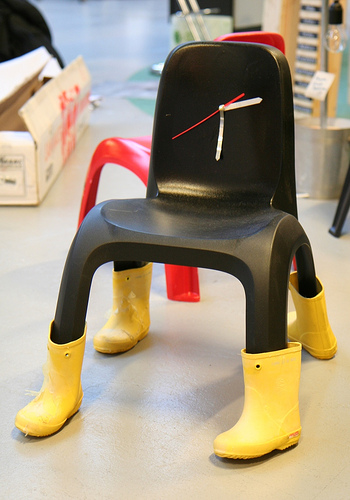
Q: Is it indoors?
A: Yes, it is indoors.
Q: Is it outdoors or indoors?
A: It is indoors.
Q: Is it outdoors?
A: No, it is indoors.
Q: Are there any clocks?
A: Yes, there is a clock.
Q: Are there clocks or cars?
A: Yes, there is a clock.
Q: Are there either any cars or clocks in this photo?
A: Yes, there is a clock.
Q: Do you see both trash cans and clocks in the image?
A: No, there is a clock but no trash cans.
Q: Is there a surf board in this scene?
A: No, there are no surfboards.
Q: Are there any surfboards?
A: No, there are no surfboards.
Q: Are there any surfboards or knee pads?
A: No, there are no surfboards or knee pads.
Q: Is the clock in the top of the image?
A: Yes, the clock is in the top of the image.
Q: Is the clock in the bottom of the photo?
A: No, the clock is in the top of the image.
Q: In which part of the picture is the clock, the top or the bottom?
A: The clock is in the top of the image.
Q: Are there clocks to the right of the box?
A: Yes, there is a clock to the right of the box.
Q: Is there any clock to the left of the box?
A: No, the clock is to the right of the box.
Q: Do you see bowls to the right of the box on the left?
A: No, there is a clock to the right of the box.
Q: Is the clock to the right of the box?
A: Yes, the clock is to the right of the box.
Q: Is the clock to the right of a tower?
A: No, the clock is to the right of the box.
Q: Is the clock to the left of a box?
A: No, the clock is to the right of a box.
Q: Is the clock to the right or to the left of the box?
A: The clock is to the right of the box.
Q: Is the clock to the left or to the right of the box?
A: The clock is to the right of the box.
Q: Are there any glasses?
A: No, there are no glasses.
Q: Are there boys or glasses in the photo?
A: No, there are no glasses or boys.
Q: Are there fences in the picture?
A: No, there are no fences.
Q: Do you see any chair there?
A: Yes, there is a chair.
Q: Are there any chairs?
A: Yes, there is a chair.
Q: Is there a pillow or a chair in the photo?
A: Yes, there is a chair.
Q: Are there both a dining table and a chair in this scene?
A: No, there is a chair but no dining tables.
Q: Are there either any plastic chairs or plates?
A: Yes, there is a plastic chair.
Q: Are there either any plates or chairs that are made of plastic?
A: Yes, the chair is made of plastic.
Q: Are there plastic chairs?
A: Yes, there is a chair that is made of plastic.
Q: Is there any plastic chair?
A: Yes, there is a chair that is made of plastic.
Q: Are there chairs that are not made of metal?
A: Yes, there is a chair that is made of plastic.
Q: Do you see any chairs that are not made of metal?
A: Yes, there is a chair that is made of plastic.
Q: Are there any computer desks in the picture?
A: No, there are no computer desks.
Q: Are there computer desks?
A: No, there are no computer desks.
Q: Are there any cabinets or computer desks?
A: No, there are no computer desks or cabinets.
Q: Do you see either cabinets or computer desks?
A: No, there are no computer desks or cabinets.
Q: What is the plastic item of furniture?
A: The piece of furniture is a chair.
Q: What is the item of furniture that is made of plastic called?
A: The piece of furniture is a chair.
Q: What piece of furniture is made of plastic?
A: The piece of furniture is a chair.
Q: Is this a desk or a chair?
A: This is a chair.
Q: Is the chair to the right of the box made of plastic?
A: Yes, the chair is made of plastic.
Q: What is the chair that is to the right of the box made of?
A: The chair is made of plastic.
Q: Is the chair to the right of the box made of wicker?
A: No, the chair is made of plastic.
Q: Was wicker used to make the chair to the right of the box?
A: No, the chair is made of plastic.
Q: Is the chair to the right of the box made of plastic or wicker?
A: The chair is made of plastic.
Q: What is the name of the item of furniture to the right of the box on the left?
A: The piece of furniture is a chair.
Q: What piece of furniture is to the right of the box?
A: The piece of furniture is a chair.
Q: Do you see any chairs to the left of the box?
A: No, the chair is to the right of the box.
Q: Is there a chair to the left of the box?
A: No, the chair is to the right of the box.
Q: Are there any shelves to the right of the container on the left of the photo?
A: No, there is a chair to the right of the box.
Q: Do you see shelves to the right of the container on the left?
A: No, there is a chair to the right of the box.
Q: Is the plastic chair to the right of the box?
A: Yes, the chair is to the right of the box.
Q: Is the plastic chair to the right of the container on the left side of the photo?
A: Yes, the chair is to the right of the box.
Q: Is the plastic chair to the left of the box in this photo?
A: No, the chair is to the right of the box.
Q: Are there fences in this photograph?
A: No, there are no fences.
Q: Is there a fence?
A: No, there are no fences.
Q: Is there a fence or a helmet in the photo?
A: No, there are no fences or helmets.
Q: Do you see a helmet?
A: No, there are no helmets.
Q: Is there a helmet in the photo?
A: No, there are no helmets.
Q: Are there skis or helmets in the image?
A: No, there are no helmets or skis.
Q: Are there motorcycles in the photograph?
A: No, there are no motorcycles.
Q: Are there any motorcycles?
A: No, there are no motorcycles.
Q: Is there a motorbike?
A: No, there are no motorcycles.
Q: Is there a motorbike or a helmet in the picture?
A: No, there are no motorcycles or helmets.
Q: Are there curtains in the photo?
A: No, there are no curtains.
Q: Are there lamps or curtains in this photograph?
A: No, there are no curtains or lamps.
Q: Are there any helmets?
A: No, there are no helmets.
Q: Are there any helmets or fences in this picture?
A: No, there are no helmets or fences.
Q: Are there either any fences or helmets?
A: No, there are no helmets or fences.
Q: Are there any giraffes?
A: No, there are no giraffes.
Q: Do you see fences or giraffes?
A: No, there are no giraffes or fences.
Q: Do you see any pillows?
A: No, there are no pillows.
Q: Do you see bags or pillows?
A: No, there are no pillows or bags.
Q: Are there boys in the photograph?
A: No, there are no boys.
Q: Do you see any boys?
A: No, there are no boys.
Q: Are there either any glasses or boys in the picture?
A: No, there are no boys or glasses.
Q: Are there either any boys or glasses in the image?
A: No, there are no boys or glasses.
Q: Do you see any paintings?
A: No, there are no paintings.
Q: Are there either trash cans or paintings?
A: No, there are no paintings or trash cans.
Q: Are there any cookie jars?
A: No, there are no cookie jars.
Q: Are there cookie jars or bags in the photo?
A: No, there are no cookie jars or bags.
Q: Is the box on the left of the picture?
A: Yes, the box is on the left of the image.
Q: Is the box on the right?
A: No, the box is on the left of the image.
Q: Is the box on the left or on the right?
A: The box is on the left of the image.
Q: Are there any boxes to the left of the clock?
A: Yes, there is a box to the left of the clock.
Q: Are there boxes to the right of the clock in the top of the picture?
A: No, the box is to the left of the clock.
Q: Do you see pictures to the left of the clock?
A: No, there is a box to the left of the clock.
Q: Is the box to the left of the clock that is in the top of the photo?
A: Yes, the box is to the left of the clock.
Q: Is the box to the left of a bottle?
A: No, the box is to the left of the clock.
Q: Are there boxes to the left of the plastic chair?
A: Yes, there is a box to the left of the chair.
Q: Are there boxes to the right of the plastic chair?
A: No, the box is to the left of the chair.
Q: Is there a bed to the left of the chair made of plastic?
A: No, there is a box to the left of the chair.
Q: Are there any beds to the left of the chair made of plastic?
A: No, there is a box to the left of the chair.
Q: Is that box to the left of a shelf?
A: No, the box is to the left of a chair.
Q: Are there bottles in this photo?
A: No, there are no bottles.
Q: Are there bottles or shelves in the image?
A: No, there are no bottles or shelves.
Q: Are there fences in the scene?
A: No, there are no fences.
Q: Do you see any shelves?
A: No, there are no shelves.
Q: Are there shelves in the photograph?
A: No, there are no shelves.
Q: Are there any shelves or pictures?
A: No, there are no shelves or pictures.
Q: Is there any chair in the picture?
A: Yes, there is a chair.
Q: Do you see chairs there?
A: Yes, there is a chair.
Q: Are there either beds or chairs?
A: Yes, there is a chair.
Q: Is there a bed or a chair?
A: Yes, there is a chair.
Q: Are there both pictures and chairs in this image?
A: No, there is a chair but no pictures.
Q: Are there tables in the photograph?
A: No, there are no tables.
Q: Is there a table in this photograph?
A: No, there are no tables.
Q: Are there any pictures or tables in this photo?
A: No, there are no tables or pictures.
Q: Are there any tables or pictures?
A: No, there are no tables or pictures.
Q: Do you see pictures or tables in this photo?
A: No, there are no tables or pictures.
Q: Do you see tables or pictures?
A: No, there are no tables or pictures.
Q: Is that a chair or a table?
A: That is a chair.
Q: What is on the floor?
A: The chair is on the floor.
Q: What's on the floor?
A: The chair is on the floor.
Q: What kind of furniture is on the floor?
A: The piece of furniture is a chair.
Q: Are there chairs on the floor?
A: Yes, there is a chair on the floor.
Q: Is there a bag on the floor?
A: No, there is a chair on the floor.